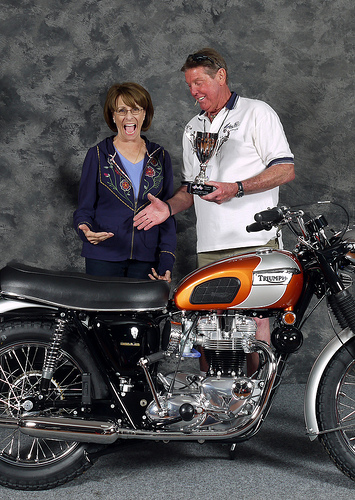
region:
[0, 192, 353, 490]
Orange and grey triumph motorcycle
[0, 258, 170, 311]
black motorcycle seat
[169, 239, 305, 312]
orange and grey motorcycle tant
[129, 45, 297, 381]
man in white shirt getting ready to shake womans hand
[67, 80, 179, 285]
woman in blue decorative jacket with shocked look on her face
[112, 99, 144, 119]
womans eyeglasses that she is wearing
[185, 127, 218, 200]
trophy the man is holding in his hand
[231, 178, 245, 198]
watch the man is wearing on his hand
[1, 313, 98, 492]
back motorcycle tire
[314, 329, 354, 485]
front motorcycle tire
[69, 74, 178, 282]
woman with her mouth open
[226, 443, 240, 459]
kickstand of the motorcycle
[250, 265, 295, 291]
silver logo on the side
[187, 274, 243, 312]
black on the bike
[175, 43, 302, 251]
man with white shirt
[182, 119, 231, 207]
trophy in the mans hand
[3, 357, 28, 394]
spokes on the bike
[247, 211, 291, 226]
handlebar of the bike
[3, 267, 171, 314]
black seat on the bike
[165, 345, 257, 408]
motor of the bike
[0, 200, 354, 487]
a black and orange motorcycle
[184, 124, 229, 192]
a silver trophy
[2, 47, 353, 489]
a man and woman standing next to motorcycle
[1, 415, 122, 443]
a chrome exhaust pipe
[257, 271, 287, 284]
printed Triumph logo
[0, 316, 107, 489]
a motorcycle rear wheel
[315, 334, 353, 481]
a motorcycle front tire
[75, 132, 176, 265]
a decorated blue jacket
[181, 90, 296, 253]
a white and blue shirt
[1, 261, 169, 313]
a black leather seat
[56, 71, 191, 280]
lady standing with motorcycle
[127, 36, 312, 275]
man standing next to motorcycle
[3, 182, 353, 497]
orange and silver motorcycle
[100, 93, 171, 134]
lady wearing glasses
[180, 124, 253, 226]
man holding trophy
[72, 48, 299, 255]
man and lady standing with motorcycle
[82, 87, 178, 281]
lady wearing navy blue jacket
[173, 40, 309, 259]
man wearing white shirt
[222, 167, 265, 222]
man wearing black watch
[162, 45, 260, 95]
man wearing glasses on head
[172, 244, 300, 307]
orange and silver gas tank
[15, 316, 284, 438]
chrome exhaust pipe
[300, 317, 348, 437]
silver fender of front wheel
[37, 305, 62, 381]
spring supporting seat for rider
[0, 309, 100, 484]
black wall tires on bike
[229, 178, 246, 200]
black wrist watch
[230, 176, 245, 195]
purple jacket floral embroidery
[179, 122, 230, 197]
a winner's cup trophy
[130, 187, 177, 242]
reaching out to shake hands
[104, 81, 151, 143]
a happily surprised face